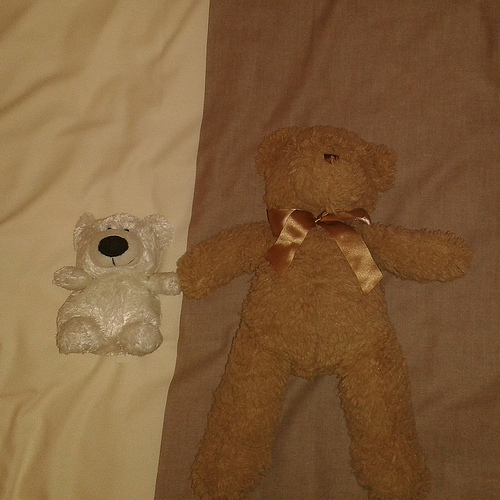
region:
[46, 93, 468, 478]
two bears on bed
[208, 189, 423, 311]
bear has brown bow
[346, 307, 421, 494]
bear has brown leg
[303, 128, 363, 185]
bear has brown nose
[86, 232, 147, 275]
bear has black nose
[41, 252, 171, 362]
bear has short legs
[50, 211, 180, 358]
a small white teddy bear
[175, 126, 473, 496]
a large brown teddy bear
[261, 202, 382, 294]
a gold color bow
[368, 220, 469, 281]
a brown teddy bear's left arm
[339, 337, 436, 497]
a brown teddy bear's left leg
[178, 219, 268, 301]
a brown teddy bear's right arm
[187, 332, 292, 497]
a brown teddy bear's right leg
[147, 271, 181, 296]
a white teddy bear's left arm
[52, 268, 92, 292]
a white teddy bear's right arm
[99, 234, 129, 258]
a white teddy bear's black nose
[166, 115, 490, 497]
this is a teddy bear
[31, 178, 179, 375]
this is a white bear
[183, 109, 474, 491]
the teddy bear is brown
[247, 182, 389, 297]
a bow on the bear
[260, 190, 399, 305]
the ribbon is satin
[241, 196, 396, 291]
the ribbon is brown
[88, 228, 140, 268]
black nose on bear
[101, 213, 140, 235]
black eyes on bear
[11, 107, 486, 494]
two bears laying down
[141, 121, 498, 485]
brown fabric under bear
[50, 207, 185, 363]
white stuffed bear on blanket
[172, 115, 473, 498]
brown stuffed bear on blanket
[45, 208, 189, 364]
white bear toy on white blanket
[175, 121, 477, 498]
brown bear toy on brown blanket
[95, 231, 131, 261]
black bear nose on bear toy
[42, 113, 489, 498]
two toy bears laying side by side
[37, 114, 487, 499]
two toy bears holding hands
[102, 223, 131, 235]
black eyes on white toy bear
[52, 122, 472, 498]
two teddy bears laying face up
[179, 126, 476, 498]
brown bear with ribbon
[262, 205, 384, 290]
ribbon tied in a bow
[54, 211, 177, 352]
white bear with black nose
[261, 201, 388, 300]
tie on a teddy bear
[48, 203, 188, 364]
small white teddy bear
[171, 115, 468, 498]
big brown teddy bear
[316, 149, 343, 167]
nose on a brown teddy bear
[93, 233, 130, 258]
nose on a white bear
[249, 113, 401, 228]
head of a brown teddy bear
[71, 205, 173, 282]
head of a white teddy bear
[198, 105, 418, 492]
A toy stuffed animal.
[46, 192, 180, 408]
A toy stuffed animal.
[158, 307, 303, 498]
A limb on a stuffed animal.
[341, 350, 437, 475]
A limb on a stuffed animal.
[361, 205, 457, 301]
A limb on a stuffed animal.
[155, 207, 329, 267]
A limb on a stuffed animal.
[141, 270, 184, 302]
A limb on a stuffed animal.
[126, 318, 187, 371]
A limb on a stuffed animal.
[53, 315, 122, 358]
A limb on a stuffed animal.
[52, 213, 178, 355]
the stuffed bear is white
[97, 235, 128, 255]
the nose is black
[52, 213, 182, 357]
the black nose on the white bear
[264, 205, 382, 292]
the ribbon is gold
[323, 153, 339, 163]
the nose is brown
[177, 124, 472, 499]
the bear is light brown